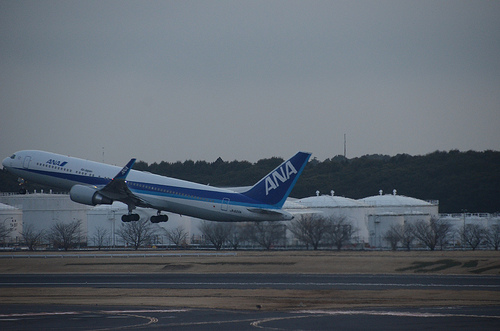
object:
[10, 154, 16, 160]
windows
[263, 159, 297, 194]
ana logo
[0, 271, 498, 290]
runway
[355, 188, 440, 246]
buildings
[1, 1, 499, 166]
sky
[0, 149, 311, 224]
airplane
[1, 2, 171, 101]
air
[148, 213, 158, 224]
wheels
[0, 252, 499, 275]
grass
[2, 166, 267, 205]
stripe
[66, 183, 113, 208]
engine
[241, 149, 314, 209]
tail